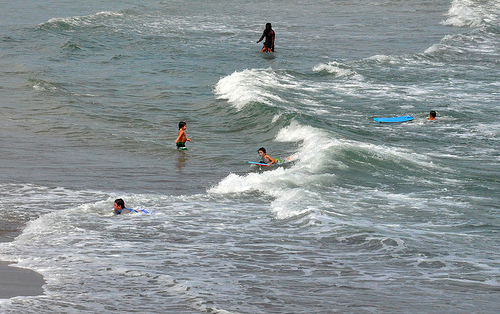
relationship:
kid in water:
[251, 146, 286, 180] [22, 63, 90, 130]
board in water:
[371, 101, 419, 139] [22, 63, 90, 130]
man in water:
[255, 23, 284, 57] [22, 63, 90, 130]